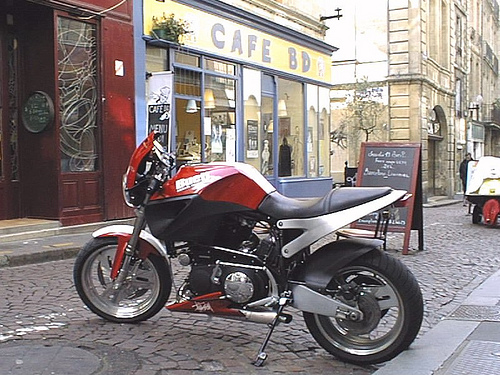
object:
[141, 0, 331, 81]
sign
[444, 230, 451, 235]
cobblestone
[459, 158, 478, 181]
shirt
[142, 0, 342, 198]
cafe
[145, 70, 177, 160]
banner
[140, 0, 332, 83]
wall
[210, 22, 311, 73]
restaurant`s name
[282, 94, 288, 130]
glass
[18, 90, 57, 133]
sign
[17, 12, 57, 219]
wall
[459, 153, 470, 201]
person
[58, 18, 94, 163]
glass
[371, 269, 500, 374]
curb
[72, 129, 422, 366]
motorcycle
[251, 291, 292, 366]
kick stand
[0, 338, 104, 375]
manhole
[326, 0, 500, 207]
building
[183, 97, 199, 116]
shade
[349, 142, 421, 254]
sign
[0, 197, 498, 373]
road